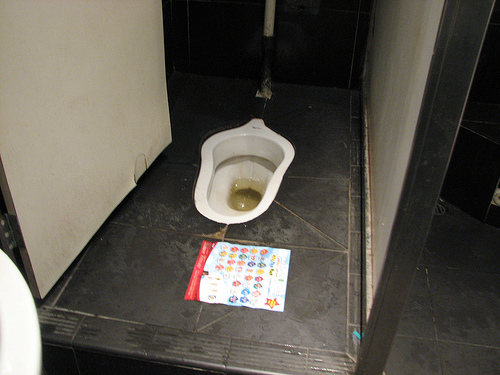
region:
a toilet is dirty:
[188, 108, 299, 231]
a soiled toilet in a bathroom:
[8, 5, 498, 370]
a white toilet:
[188, 115, 302, 227]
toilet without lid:
[188, 109, 300, 234]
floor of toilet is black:
[45, 114, 360, 374]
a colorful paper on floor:
[171, 228, 298, 325]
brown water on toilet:
[223, 170, 270, 213]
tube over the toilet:
[250, 0, 285, 120]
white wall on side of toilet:
[10, 5, 172, 266]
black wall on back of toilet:
[164, 2, 368, 157]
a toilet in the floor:
[187, 103, 302, 224]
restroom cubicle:
[3, 3, 403, 357]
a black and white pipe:
[236, 0, 312, 108]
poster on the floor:
[183, 239, 300, 319]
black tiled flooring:
[79, 215, 186, 322]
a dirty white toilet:
[191, 110, 305, 229]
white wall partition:
[0, 4, 154, 274]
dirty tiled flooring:
[116, 185, 197, 321]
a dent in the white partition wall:
[119, 131, 160, 195]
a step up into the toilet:
[42, 297, 167, 374]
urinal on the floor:
[195, 88, 301, 243]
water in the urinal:
[224, 168, 264, 222]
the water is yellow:
[221, 165, 263, 214]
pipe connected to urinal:
[241, 3, 298, 130]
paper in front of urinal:
[186, 226, 313, 326]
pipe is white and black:
[261, 2, 289, 125]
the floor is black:
[92, 153, 379, 373]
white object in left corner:
[3, 246, 65, 366]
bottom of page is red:
[183, 233, 215, 323]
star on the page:
[263, 289, 285, 319]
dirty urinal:
[191, 85, 305, 237]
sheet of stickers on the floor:
[185, 232, 295, 322]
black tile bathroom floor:
[108, 229, 179, 307]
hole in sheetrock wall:
[120, 148, 162, 191]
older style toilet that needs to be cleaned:
[157, 3, 333, 236]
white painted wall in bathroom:
[378, 103, 403, 143]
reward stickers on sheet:
[185, 226, 300, 326]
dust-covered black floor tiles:
[442, 272, 493, 324]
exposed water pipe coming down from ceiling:
[248, 2, 289, 116]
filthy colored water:
[225, 175, 258, 206]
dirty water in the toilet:
[220, 171, 275, 219]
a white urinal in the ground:
[196, 112, 301, 227]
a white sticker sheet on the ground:
[187, 230, 292, 318]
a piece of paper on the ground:
[153, 228, 321, 333]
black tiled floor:
[57, 84, 357, 358]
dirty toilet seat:
[177, 113, 304, 235]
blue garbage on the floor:
[347, 328, 367, 343]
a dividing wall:
[361, 1, 483, 367]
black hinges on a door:
[0, 209, 21, 256]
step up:
[38, 307, 355, 374]